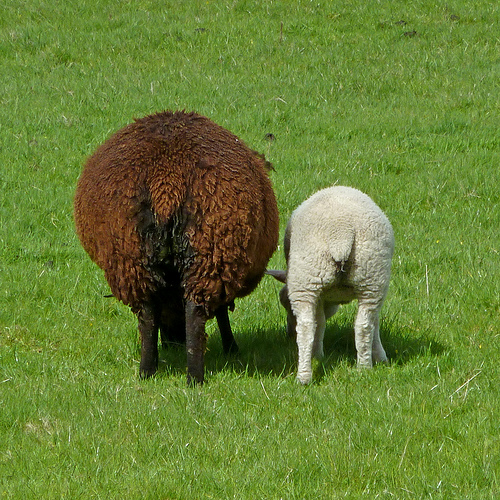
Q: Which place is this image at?
A: It is at the field.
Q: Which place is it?
A: It is a field.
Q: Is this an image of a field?
A: Yes, it is showing a field.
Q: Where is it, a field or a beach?
A: It is a field.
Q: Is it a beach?
A: No, it is a field.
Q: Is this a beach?
A: No, it is a field.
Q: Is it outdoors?
A: Yes, it is outdoors.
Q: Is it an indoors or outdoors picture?
A: It is outdoors.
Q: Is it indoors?
A: No, it is outdoors.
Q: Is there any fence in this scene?
A: No, there are no fences.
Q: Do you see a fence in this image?
A: No, there are no fences.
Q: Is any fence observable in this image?
A: No, there are no fences.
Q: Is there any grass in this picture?
A: Yes, there is grass.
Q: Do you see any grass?
A: Yes, there is grass.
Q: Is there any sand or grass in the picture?
A: Yes, there is grass.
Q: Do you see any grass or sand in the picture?
A: Yes, there is grass.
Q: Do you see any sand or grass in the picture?
A: Yes, there is grass.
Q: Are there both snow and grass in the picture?
A: No, there is grass but no snow.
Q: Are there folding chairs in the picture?
A: No, there are no folding chairs.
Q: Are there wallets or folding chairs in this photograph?
A: No, there are no folding chairs or wallets.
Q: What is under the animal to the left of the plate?
A: The grass is under the animal.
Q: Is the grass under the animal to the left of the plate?
A: Yes, the grass is under the animal.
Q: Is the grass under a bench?
A: No, the grass is under the animal.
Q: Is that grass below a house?
A: No, the grass is below an animal.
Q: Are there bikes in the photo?
A: No, there are no bikes.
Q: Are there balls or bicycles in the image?
A: No, there are no bicycles or balls.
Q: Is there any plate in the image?
A: Yes, there is a plate.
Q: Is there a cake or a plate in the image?
A: Yes, there is a plate.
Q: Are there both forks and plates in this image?
A: No, there is a plate but no forks.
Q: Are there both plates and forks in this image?
A: No, there is a plate but no forks.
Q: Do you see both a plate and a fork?
A: No, there is a plate but no forks.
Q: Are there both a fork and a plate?
A: No, there is a plate but no forks.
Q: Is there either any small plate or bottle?
A: Yes, there is a small plate.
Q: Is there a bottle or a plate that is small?
A: Yes, the plate is small.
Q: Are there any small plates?
A: Yes, there is a small plate.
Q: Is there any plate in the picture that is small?
A: Yes, there is a plate that is small.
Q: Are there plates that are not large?
A: Yes, there is a small plate.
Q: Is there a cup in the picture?
A: No, there are no cups.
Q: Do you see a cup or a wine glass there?
A: No, there are no cups or wine glasses.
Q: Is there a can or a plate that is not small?
A: No, there is a plate but it is small.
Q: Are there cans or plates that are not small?
A: No, there is a plate but it is small.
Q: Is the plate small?
A: Yes, the plate is small.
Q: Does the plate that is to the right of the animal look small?
A: Yes, the plate is small.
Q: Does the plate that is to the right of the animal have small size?
A: Yes, the plate is small.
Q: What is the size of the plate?
A: The plate is small.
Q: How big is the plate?
A: The plate is small.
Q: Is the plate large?
A: No, the plate is small.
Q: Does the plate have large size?
A: No, the plate is small.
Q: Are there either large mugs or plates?
A: No, there is a plate but it is small.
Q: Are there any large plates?
A: No, there is a plate but it is small.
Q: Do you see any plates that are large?
A: No, there is a plate but it is small.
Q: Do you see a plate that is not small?
A: No, there is a plate but it is small.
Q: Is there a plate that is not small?
A: No, there is a plate but it is small.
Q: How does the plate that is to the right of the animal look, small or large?
A: The plate is small.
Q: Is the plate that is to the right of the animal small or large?
A: The plate is small.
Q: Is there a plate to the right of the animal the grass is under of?
A: Yes, there is a plate to the right of the animal.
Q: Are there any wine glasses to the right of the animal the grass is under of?
A: No, there is a plate to the right of the animal.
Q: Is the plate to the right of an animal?
A: Yes, the plate is to the right of an animal.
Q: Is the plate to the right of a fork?
A: No, the plate is to the right of an animal.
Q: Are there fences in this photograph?
A: No, there are no fences.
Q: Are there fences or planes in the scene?
A: No, there are no fences or planes.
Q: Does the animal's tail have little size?
A: Yes, the tail is little.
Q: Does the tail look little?
A: Yes, the tail is little.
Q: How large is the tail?
A: The tail is little.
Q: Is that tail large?
A: No, the tail is little.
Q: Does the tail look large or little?
A: The tail is little.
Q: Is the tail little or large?
A: The tail is little.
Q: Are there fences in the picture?
A: No, there are no fences.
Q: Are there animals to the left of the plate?
A: Yes, there is an animal to the left of the plate.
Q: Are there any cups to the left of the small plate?
A: No, there is an animal to the left of the plate.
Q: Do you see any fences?
A: No, there are no fences.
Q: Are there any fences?
A: No, there are no fences.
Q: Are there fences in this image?
A: No, there are no fences.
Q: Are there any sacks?
A: No, there are no sacks.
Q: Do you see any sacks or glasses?
A: No, there are no sacks or glasses.